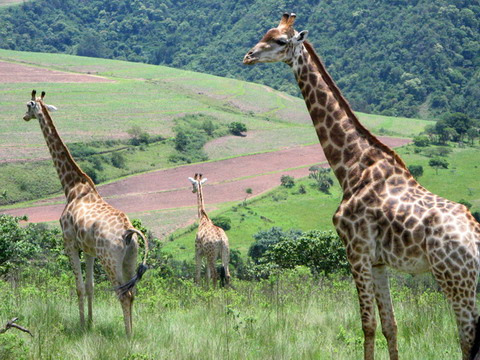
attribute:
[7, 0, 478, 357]
field — open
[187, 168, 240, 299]
giraffe — small, facing away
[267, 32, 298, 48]
eye — giraffe's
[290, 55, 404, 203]
neck — long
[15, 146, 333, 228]
path — dirt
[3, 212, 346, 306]
shrubbery — short, green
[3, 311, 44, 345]
twig — brown, fallen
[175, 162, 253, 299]
giraffe — furthest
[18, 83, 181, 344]
giraffe — tall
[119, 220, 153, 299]
tail — brown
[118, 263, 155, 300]
hair — black, puff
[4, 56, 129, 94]
area — dirt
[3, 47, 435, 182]
hill — green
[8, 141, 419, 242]
field — large, empty, dirt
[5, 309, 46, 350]
branch — bare, dead, brown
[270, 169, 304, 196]
bush — short, round, green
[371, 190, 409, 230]
spot — unique shaped, brown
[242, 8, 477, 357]
giraffe — closest, tall, large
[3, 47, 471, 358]
landscape — grass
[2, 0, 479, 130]
forest — expansive, dark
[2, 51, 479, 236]
plain — open, grassy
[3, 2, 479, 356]
savannah — grassy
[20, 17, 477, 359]
giraffes — three